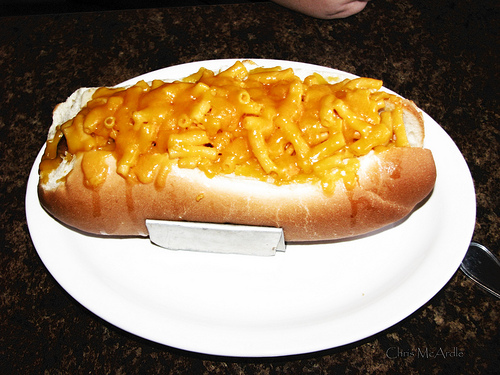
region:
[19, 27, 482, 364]
A white plate with a mac-and-cheese dog on it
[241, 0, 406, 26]
The edge of someone's hand or arm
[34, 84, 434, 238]
A hot dog covered in macaroni and cheese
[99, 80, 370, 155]
Bright yellow macaroni and cheese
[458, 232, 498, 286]
The end of a piece of silverware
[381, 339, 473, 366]
Watermark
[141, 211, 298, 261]
A napkin or holder under the hot dog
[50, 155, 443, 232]
A hot dog bun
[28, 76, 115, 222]
A small bite taken from the hot dog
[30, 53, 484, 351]
A macaroni and cheese hot dog on a white plate on a marbled table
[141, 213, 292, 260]
a piece of white paper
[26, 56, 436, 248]
a macaroni and cheese hot dog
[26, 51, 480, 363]
a white plate on the table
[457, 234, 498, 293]
a metal utensil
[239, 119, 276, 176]
a piece of macaroni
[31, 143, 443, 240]
a brown hot dog bun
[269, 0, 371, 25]
the hand of a person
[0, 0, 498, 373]
a dark marble table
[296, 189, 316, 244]
a crack in the bun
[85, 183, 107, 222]
sauce on the bun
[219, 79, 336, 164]
MAC AND CHEESE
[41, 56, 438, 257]
MAC AND CHEESE ON A BUN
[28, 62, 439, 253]
A HOT DOG COVERED IN MAC AND CHEESE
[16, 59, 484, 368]
A ROUND WHITE PLATE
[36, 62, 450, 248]
A WHITE BREAD BUN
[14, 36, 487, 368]
A HOT DOG ON A PLATE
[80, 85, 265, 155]
CHEESE ON MACARONI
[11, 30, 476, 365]
A PLATE ON A TABLE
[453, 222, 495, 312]
THE TIP OF AN EATING UTENSIL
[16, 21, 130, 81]
A MARBLE TABLETOP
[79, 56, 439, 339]
The hot dog sits on the plate.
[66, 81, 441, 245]
The hotdog has mac and cheese on top.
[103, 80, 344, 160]
The mac and cheese is orange.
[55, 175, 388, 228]
The bun is toasted.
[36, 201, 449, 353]
The plate is white.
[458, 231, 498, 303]
Part of silverware in the corner.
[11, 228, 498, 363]
the table is black marble.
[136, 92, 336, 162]
The cheese looks very cheesy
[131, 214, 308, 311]
A piece of paper next to the hotdog.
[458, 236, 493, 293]
The utensil is silver.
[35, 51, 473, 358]
a white plate holding food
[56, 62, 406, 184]
the macaroni and cheese on top of the hot dog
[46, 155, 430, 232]
part of the hot dog bun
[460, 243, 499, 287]
part of the utensil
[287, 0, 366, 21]
part of the napkin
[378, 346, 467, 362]
the name of the photographer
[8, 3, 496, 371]
the table the food is sitting on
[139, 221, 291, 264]
a paper propping up the food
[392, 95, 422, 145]
another part of the bun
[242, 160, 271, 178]
some cheese on the bun